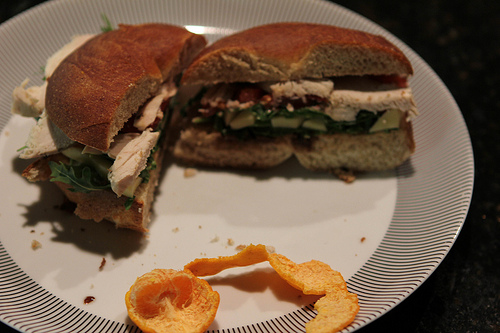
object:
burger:
[171, 19, 418, 173]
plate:
[0, 0, 478, 333]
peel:
[189, 234, 364, 332]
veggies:
[270, 115, 302, 128]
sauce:
[80, 291, 100, 307]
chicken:
[269, 78, 414, 112]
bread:
[181, 20, 419, 85]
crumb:
[182, 165, 201, 179]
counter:
[0, 0, 500, 333]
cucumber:
[229, 113, 259, 130]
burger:
[24, 20, 204, 241]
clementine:
[120, 267, 221, 332]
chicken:
[14, 29, 103, 117]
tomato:
[235, 84, 263, 103]